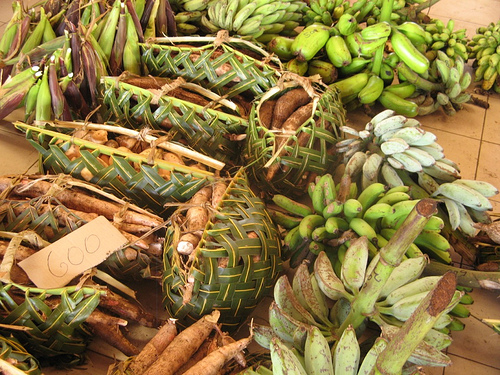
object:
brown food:
[176, 336, 252, 375]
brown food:
[267, 87, 311, 134]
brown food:
[141, 310, 219, 375]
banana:
[269, 335, 311, 375]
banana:
[344, 197, 362, 225]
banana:
[364, 203, 396, 230]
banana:
[341, 236, 369, 294]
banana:
[296, 214, 322, 241]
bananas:
[303, 327, 337, 374]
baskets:
[161, 168, 285, 338]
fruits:
[377, 91, 420, 117]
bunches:
[367, 271, 457, 375]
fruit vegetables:
[269, 193, 311, 220]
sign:
[14, 215, 129, 300]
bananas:
[356, 72, 383, 105]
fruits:
[446, 304, 471, 320]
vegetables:
[120, 3, 141, 74]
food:
[391, 30, 431, 75]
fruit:
[18, 15, 43, 54]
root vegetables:
[273, 88, 307, 131]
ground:
[0, 0, 500, 375]